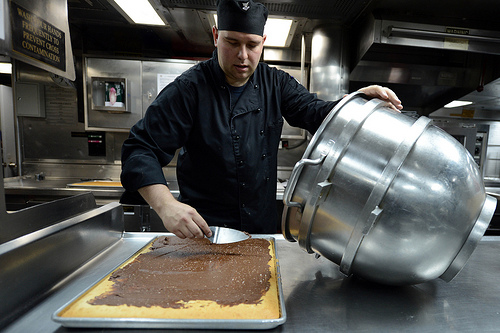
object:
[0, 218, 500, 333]
table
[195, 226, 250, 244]
spatula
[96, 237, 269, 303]
sauce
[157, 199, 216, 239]
hand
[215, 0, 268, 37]
hat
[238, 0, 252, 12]
pin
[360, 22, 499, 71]
system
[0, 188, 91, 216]
pan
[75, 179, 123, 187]
dessert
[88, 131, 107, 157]
object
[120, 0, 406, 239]
chef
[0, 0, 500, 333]
kitchen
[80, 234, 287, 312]
frosting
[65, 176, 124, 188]
pan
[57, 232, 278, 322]
cake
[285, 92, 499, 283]
bin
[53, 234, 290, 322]
pan